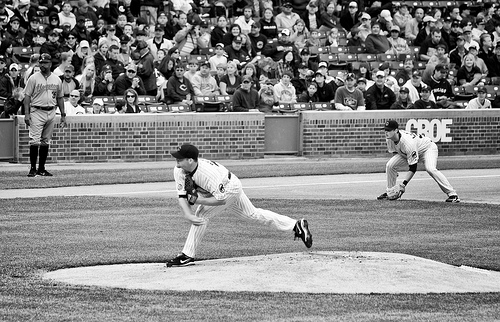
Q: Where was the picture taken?
A: It was taken at the field.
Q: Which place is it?
A: It is a field.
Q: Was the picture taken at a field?
A: Yes, it was taken in a field.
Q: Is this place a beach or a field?
A: It is a field.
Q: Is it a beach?
A: No, it is a field.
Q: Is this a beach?
A: No, it is a field.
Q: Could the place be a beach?
A: No, it is a field.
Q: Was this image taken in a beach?
A: No, the picture was taken in a field.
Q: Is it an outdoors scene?
A: Yes, it is outdoors.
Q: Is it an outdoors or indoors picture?
A: It is outdoors.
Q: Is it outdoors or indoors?
A: It is outdoors.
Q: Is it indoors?
A: No, it is outdoors.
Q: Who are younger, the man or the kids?
A: The kids are younger than the man.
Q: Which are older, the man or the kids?
A: The man are older than the kids.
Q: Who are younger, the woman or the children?
A: The children are younger than the woman.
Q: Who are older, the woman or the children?
A: The woman are older than the children.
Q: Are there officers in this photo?
A: No, there are no officers.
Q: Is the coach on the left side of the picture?
A: Yes, the coach is on the left of the image.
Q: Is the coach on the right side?
A: No, the coach is on the left of the image.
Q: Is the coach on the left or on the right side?
A: The coach is on the left of the image.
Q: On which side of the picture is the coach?
A: The coach is on the left of the image.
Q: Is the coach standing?
A: Yes, the coach is standing.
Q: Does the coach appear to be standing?
A: Yes, the coach is standing.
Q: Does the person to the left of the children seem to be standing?
A: Yes, the coach is standing.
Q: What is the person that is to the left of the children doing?
A: The coach is standing.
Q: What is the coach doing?
A: The coach is standing.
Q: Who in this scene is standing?
A: The coach is standing.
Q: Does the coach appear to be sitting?
A: No, the coach is standing.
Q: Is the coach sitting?
A: No, the coach is standing.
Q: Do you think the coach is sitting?
A: No, the coach is standing.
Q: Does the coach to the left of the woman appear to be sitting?
A: No, the coach is standing.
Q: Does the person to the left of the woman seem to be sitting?
A: No, the coach is standing.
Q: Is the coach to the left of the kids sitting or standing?
A: The coach is standing.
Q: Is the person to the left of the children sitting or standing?
A: The coach is standing.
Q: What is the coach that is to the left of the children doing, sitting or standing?
A: The coach is standing.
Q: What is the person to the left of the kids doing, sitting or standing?
A: The coach is standing.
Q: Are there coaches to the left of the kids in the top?
A: Yes, there is a coach to the left of the children.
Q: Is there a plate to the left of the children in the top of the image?
A: No, there is a coach to the left of the children.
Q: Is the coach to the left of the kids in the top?
A: Yes, the coach is to the left of the kids.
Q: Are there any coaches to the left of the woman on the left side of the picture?
A: Yes, there is a coach to the left of the woman.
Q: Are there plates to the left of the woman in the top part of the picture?
A: No, there is a coach to the left of the woman.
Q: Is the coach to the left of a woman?
A: Yes, the coach is to the left of a woman.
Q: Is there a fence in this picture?
A: No, there are no fences.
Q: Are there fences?
A: No, there are no fences.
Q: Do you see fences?
A: No, there are no fences.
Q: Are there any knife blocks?
A: No, there are no knife blocks.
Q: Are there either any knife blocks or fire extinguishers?
A: No, there are no knife blocks or fire extinguishers.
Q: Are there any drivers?
A: No, there are no drivers.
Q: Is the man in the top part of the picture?
A: Yes, the man is in the top of the image.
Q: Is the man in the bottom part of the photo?
A: No, the man is in the top of the image.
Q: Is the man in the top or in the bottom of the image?
A: The man is in the top of the image.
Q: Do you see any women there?
A: Yes, there is a woman.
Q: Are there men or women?
A: Yes, there is a woman.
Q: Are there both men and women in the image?
A: Yes, there are both a woman and a man.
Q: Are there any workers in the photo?
A: No, there are no workers.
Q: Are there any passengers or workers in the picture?
A: No, there are no workers or passengers.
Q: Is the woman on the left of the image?
A: Yes, the woman is on the left of the image.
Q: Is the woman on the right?
A: No, the woman is on the left of the image.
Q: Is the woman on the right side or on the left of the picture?
A: The woman is on the left of the image.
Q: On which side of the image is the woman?
A: The woman is on the left of the image.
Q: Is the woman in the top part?
A: Yes, the woman is in the top of the image.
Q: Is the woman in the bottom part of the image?
A: No, the woman is in the top of the image.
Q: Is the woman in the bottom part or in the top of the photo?
A: The woman is in the top of the image.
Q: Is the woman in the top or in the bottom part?
A: The woman is in the top of the image.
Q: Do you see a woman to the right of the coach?
A: Yes, there is a woman to the right of the coach.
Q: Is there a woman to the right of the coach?
A: Yes, there is a woman to the right of the coach.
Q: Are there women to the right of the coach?
A: Yes, there is a woman to the right of the coach.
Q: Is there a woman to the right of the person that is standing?
A: Yes, there is a woman to the right of the coach.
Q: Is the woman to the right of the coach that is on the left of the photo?
A: Yes, the woman is to the right of the coach.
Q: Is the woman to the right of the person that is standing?
A: Yes, the woman is to the right of the coach.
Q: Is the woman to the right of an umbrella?
A: No, the woman is to the right of the coach.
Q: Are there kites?
A: No, there are no kites.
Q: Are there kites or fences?
A: No, there are no kites or fences.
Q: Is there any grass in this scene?
A: Yes, there is grass.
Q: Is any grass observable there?
A: Yes, there is grass.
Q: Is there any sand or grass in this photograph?
A: Yes, there is grass.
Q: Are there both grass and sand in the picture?
A: No, there is grass but no sand.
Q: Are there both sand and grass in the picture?
A: No, there is grass but no sand.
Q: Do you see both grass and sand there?
A: No, there is grass but no sand.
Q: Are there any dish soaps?
A: No, there are no dish soaps.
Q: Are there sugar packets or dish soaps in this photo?
A: No, there are no dish soaps or sugar packets.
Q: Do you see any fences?
A: No, there are no fences.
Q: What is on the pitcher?
A: The cap is on the pitcher.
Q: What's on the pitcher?
A: The cap is on the pitcher.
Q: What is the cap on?
A: The cap is on the pitcher.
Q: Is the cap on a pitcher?
A: Yes, the cap is on a pitcher.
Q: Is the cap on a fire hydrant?
A: No, the cap is on a pitcher.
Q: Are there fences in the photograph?
A: No, there are no fences.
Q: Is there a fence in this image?
A: No, there are no fences.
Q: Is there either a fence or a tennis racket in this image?
A: No, there are no fences or rackets.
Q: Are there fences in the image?
A: No, there are no fences.